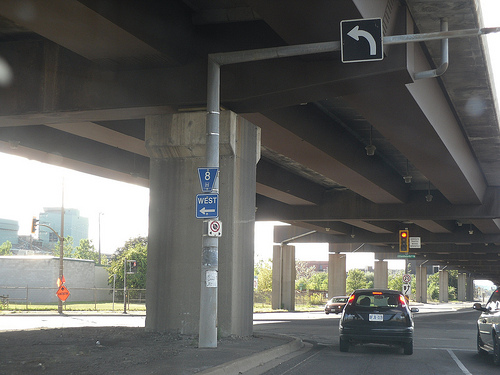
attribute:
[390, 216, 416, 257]
signal — overhead, traffic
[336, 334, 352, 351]
wheel — black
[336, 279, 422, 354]
car — black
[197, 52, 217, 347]
pole — metal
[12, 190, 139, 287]
buildings — tall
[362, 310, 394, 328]
plate — white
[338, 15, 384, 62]
sign — black, white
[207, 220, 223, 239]
traffic sign — white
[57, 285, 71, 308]
street sign — black, orange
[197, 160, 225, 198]
sign — blue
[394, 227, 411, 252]
traffic light — red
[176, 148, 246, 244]
sign — white, black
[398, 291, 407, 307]
light — rear, brake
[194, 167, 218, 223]
sign — blue, white